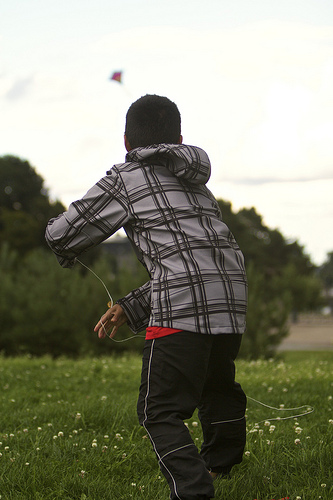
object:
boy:
[43, 92, 249, 497]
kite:
[108, 66, 126, 90]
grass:
[0, 347, 332, 499]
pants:
[136, 328, 248, 498]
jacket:
[44, 142, 248, 334]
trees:
[0, 153, 45, 212]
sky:
[0, 0, 332, 268]